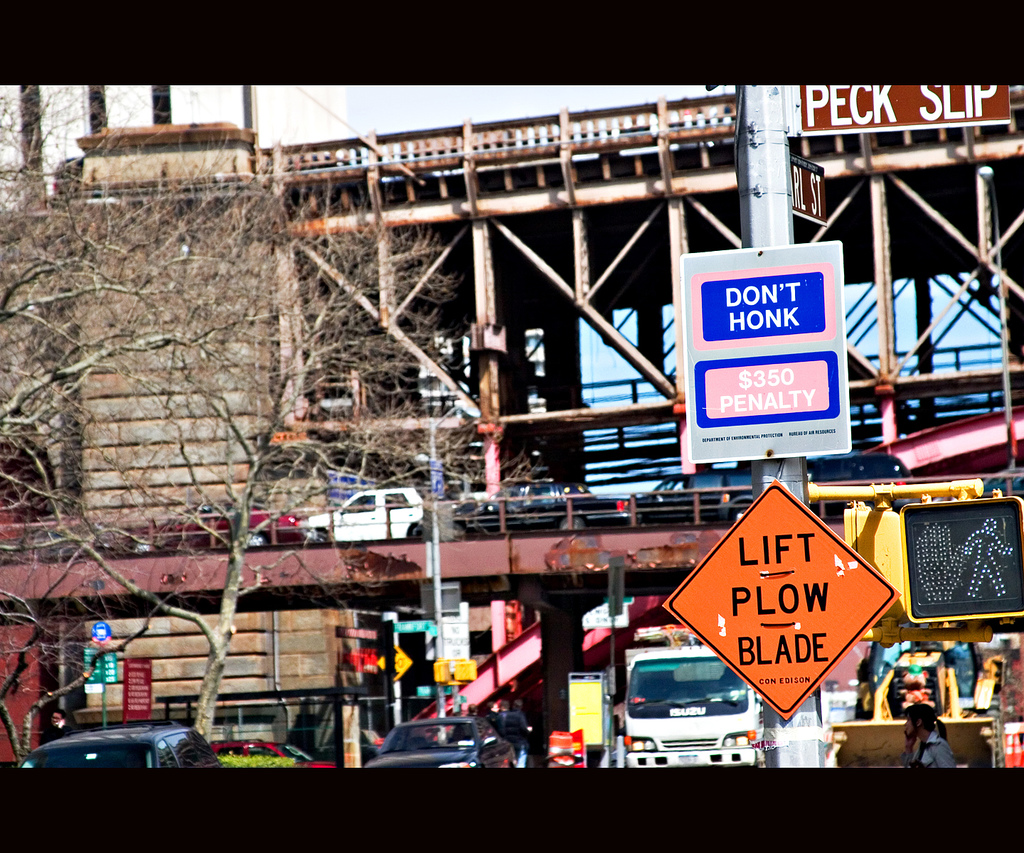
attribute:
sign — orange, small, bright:
[651, 494, 890, 729]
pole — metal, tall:
[700, 102, 838, 232]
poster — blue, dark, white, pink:
[673, 248, 881, 461]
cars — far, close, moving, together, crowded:
[310, 437, 637, 545]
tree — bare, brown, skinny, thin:
[64, 179, 412, 384]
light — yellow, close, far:
[424, 649, 490, 697]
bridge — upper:
[7, 89, 1021, 256]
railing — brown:
[271, 119, 805, 217]